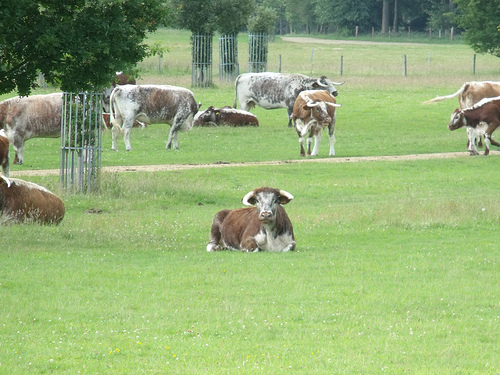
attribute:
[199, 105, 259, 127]
cow — brown-and-white, resting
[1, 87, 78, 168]
cow — brown-and-white, standing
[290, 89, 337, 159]
cow — standing, brown-and-white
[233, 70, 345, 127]
cow — brown-and-white, standing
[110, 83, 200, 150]
cow — brown-and-white, standing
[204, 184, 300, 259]
cow — cute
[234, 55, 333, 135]
cow — standing, black-and-white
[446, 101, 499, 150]
standing cow — brown-and-white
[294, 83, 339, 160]
standing cow — brown-and-white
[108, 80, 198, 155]
standing cow — brown-and-white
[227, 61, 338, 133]
standing cow — brown-and-white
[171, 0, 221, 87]
tree — grey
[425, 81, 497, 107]
cow — brown-and-white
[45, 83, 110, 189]
enclosure — metal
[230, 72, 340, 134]
cow — white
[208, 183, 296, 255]
cow — resting, brown-and-white, spotted, young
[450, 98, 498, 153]
cow — brown-and-white, young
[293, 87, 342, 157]
cow — brown-and-white, standing, young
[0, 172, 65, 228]
cow — brown-and-white, resting, standing, young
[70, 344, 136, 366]
flower — small and yellow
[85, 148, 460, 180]
strip — of bare land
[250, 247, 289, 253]
hoofs — tucked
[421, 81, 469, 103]
tail — cow's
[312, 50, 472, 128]
fence — grey